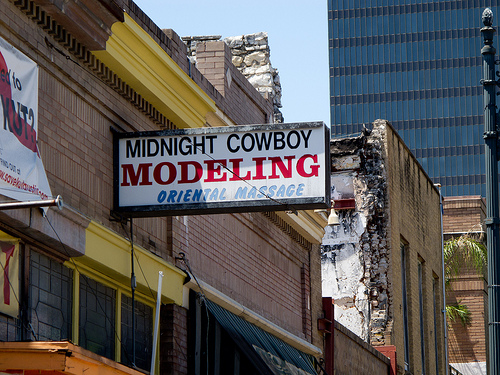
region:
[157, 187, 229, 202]
blue writing on sign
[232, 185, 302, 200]
blue writing on sign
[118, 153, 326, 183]
red writing on sign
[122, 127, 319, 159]
black writing on sign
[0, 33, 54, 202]
white sign on building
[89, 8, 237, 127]
yellow siding on wall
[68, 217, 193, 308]
yellow siding on wall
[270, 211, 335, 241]
yellow siding on wall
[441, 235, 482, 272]
green tree behind building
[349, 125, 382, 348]
broken stone wall on building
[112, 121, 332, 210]
Business sign on building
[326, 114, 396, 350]
crumbling side of brick wall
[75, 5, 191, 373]
business building with yellow trim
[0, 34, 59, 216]
banner hanging on brick wall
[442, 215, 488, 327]
palm tree sticking out between buildings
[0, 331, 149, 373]
small patio roof painted orange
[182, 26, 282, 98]
stone brick sticking out of buildling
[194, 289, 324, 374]
small black awning on business building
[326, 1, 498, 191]
tall black and blue high rise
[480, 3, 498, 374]
pine cone topped iron pole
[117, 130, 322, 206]
a white sign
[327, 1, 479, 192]
a glass building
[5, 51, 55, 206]
a white sign on the building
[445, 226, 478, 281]
a tree in front of the building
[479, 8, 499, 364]
a metal pole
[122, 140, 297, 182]
writing on the sign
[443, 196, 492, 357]
a brick building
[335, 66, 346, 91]
window of an office building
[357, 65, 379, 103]
window of an office building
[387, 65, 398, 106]
window of an office building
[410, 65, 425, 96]
window of an office building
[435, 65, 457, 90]
window of an office building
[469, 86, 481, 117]
window of an office building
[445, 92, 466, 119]
window of an office building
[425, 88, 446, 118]
window of an office building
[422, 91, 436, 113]
window of an office building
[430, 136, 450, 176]
window of an office building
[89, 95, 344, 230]
this is a storefront sign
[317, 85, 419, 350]
the building is old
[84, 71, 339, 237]
a sign to a massage parlor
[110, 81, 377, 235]
the sign is a rectangle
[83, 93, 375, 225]
the sign is white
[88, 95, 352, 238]
the sign has three colors on it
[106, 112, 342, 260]
there are three different fonts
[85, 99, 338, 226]
the the letters are capitalized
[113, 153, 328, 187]
this word is red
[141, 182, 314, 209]
this phrase is in blue letters